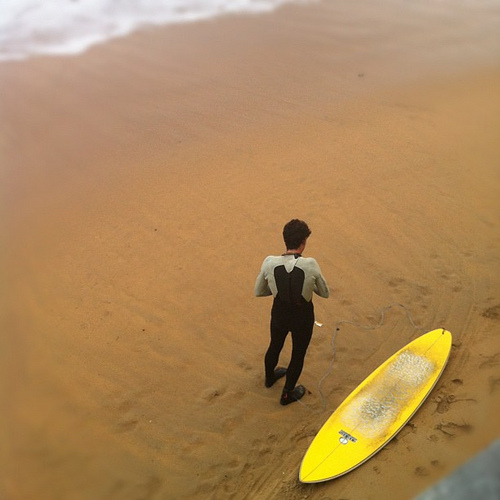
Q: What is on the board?
A: Wax.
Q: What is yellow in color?
A: Surfboard.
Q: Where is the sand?
A: On the beach.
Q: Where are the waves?
A: Beach.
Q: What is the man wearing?
A: Wetsuit.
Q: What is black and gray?
A: Wetsuit.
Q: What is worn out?
A: Surfboard.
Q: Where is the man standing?
A: On the sand.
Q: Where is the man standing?
A: Near surfboard.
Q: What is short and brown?
A: Hair.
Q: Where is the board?
A: On sand.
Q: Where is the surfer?
A: On sand.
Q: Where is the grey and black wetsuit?
A: On man.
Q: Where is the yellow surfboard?
A: On sand.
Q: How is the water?
A: Wavey.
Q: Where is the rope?
A: On surfboard.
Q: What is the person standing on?
A: Sand.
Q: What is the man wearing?
A: A black and white wetsuit.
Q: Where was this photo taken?
A: At a beach.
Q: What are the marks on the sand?
A: Footprints.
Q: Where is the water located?
A: At the top of the photo to the left.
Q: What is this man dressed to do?
A: Surf.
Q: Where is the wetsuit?
A: On the man.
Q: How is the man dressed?
A: In a wetsuit.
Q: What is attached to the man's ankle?
A: A surfboard leash.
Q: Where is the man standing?
A: On a sandy beach.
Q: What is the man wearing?
A: A wet suit.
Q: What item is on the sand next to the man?
A: A yellow surfboard.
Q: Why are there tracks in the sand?
A: People have been walking on the sand.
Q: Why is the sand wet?
A: The water has been on the sand.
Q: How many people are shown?
A: One.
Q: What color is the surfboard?
A: Yellow.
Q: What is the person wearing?
A: Wet suit.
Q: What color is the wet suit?
A: Gray and black.